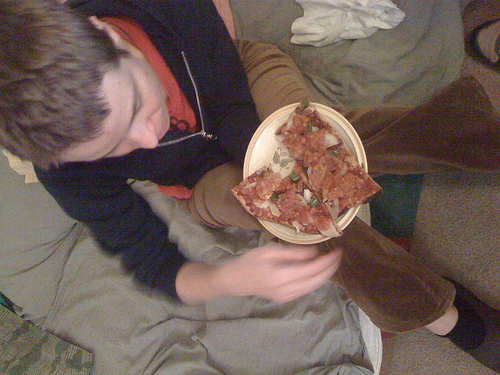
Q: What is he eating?
A: Pizza.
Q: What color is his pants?
A: Brown.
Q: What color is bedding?
A: Grey.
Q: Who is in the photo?
A: Man.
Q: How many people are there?
A: One.